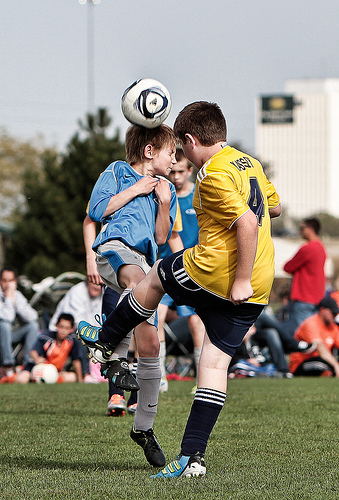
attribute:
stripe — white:
[193, 388, 226, 403]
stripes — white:
[126, 294, 160, 329]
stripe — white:
[193, 386, 228, 407]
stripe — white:
[130, 287, 155, 317]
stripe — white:
[127, 288, 169, 324]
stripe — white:
[172, 261, 190, 289]